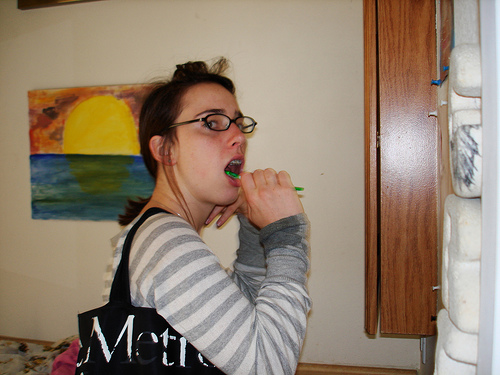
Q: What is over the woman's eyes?
A: Glasses.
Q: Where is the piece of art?
A: On the wall.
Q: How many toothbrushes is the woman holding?
A: 1.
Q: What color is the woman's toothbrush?
A: Green.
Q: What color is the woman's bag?
A: Black and white.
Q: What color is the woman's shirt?
A: Gray and white.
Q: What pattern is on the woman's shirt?
A: Stripes.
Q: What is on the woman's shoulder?
A: A bag.